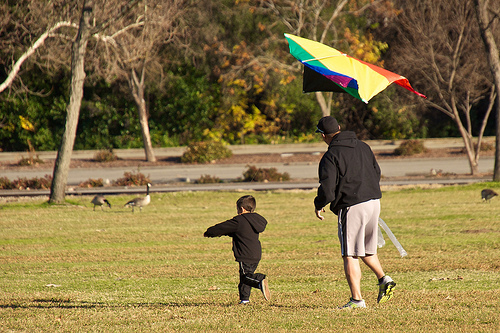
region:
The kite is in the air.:
[232, 20, 452, 120]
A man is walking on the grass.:
[301, 95, 421, 310]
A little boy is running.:
[200, 190, 285, 310]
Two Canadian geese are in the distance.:
[70, 170, 161, 215]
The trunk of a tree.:
[40, 22, 95, 209]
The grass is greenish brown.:
[17, 228, 185, 295]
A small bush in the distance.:
[171, 120, 232, 168]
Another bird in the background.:
[466, 177, 496, 210]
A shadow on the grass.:
[8, 281, 185, 317]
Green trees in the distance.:
[171, 13, 296, 135]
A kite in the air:
[272, 23, 438, 120]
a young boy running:
[198, 193, 275, 310]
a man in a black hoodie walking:
[309, 110, 403, 314]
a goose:
[123, 179, 163, 220]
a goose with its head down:
[87, 189, 116, 216]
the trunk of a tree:
[44, 13, 92, 215]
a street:
[0, 152, 498, 197]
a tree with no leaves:
[94, 3, 189, 173]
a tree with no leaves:
[381, 0, 494, 184]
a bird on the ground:
[467, 181, 497, 210]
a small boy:
[178, 185, 304, 322]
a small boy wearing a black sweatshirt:
[182, 185, 304, 302]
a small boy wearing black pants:
[192, 165, 290, 309]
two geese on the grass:
[63, 167, 189, 252]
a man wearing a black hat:
[278, 63, 390, 265]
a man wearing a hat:
[281, 114, 394, 259]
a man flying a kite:
[246, 28, 450, 316]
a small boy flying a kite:
[182, 37, 414, 332]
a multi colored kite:
[263, 6, 452, 142]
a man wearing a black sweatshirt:
[269, 120, 428, 315]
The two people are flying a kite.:
[156, 16, 446, 316]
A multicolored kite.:
[265, 15, 440, 125]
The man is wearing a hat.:
[310, 115, 345, 145]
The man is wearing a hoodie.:
[307, 130, 387, 220]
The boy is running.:
[190, 190, 290, 307]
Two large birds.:
[75, 175, 165, 220]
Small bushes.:
[67, 157, 282, 187]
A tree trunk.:
[31, 60, 88, 210]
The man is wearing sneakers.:
[335, 266, 401, 327]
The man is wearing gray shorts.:
[330, 183, 390, 260]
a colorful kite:
[278, 10, 470, 112]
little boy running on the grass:
[204, 197, 283, 313]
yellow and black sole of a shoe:
[370, 272, 403, 309]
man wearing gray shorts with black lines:
[337, 202, 396, 260]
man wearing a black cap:
[306, 103, 351, 138]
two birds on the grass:
[91, 168, 166, 219]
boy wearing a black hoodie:
[203, 212, 273, 256]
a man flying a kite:
[286, 26, 432, 313]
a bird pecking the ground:
[85, 187, 115, 219]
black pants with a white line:
[225, 258, 271, 298]